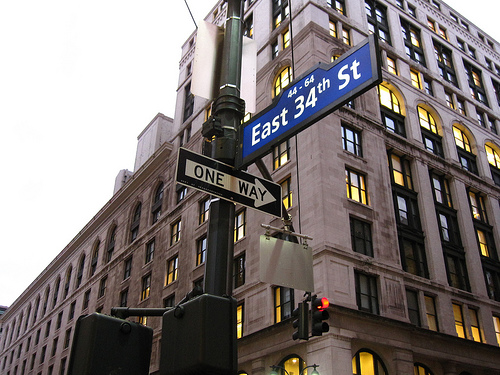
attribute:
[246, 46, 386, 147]
sign — blue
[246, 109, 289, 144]
word — white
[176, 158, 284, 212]
arrow — white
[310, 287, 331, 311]
light — red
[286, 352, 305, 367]
light — on